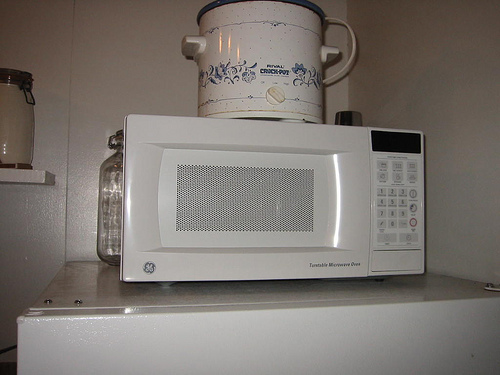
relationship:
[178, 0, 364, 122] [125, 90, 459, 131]
croc pot on top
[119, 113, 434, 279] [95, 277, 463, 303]
microwave on bottom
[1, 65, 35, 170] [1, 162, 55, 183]
glass on shelf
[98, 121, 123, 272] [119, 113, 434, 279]
glass behind microwave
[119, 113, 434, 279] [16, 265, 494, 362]
microwave on refrigerator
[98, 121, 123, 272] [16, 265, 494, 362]
jar on fridge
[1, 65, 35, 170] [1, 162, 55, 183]
jar on shelf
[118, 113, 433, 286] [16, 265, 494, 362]
microwave on refrigerator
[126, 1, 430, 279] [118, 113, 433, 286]
pair of microwave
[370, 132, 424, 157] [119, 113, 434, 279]
display of microwave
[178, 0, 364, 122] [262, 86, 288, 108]
croc pot cooker switch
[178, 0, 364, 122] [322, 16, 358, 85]
croc pot cooker cord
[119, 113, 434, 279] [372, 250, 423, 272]
microwave door button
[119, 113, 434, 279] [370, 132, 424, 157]
microwave lcd display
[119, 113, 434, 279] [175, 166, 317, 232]
microwave viewing window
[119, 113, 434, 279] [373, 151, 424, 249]
microwave control panel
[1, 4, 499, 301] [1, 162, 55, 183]
wall mounted shelf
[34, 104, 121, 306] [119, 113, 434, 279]
left of microwave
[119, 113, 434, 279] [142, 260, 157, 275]
microwave ge ge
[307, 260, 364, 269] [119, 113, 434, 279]
writing on microwave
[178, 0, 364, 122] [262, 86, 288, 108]
croc pot pot dial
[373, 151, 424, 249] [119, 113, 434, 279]
dials on microwave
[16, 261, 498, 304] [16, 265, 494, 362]
top of fridge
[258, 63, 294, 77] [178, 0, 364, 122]
logo on croc pot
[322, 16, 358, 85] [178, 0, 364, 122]
cord on croc pot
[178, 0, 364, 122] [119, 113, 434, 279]
croc pot on microwave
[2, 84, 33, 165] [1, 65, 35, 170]
white ceramic jar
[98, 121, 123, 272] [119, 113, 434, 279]
jar behind microwave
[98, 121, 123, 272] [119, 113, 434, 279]
jar near microwave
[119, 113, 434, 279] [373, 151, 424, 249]
microwave control pad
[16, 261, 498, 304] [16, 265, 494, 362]
top of refrigerator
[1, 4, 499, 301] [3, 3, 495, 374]
wall of kitchen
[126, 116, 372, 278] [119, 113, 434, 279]
door on microwave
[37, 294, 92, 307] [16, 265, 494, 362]
screws on refrigerator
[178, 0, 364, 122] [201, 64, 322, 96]
croc pot blue design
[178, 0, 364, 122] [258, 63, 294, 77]
croc pot pot logo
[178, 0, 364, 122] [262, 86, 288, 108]
croc pot control knob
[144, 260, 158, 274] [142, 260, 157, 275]
ge company ge